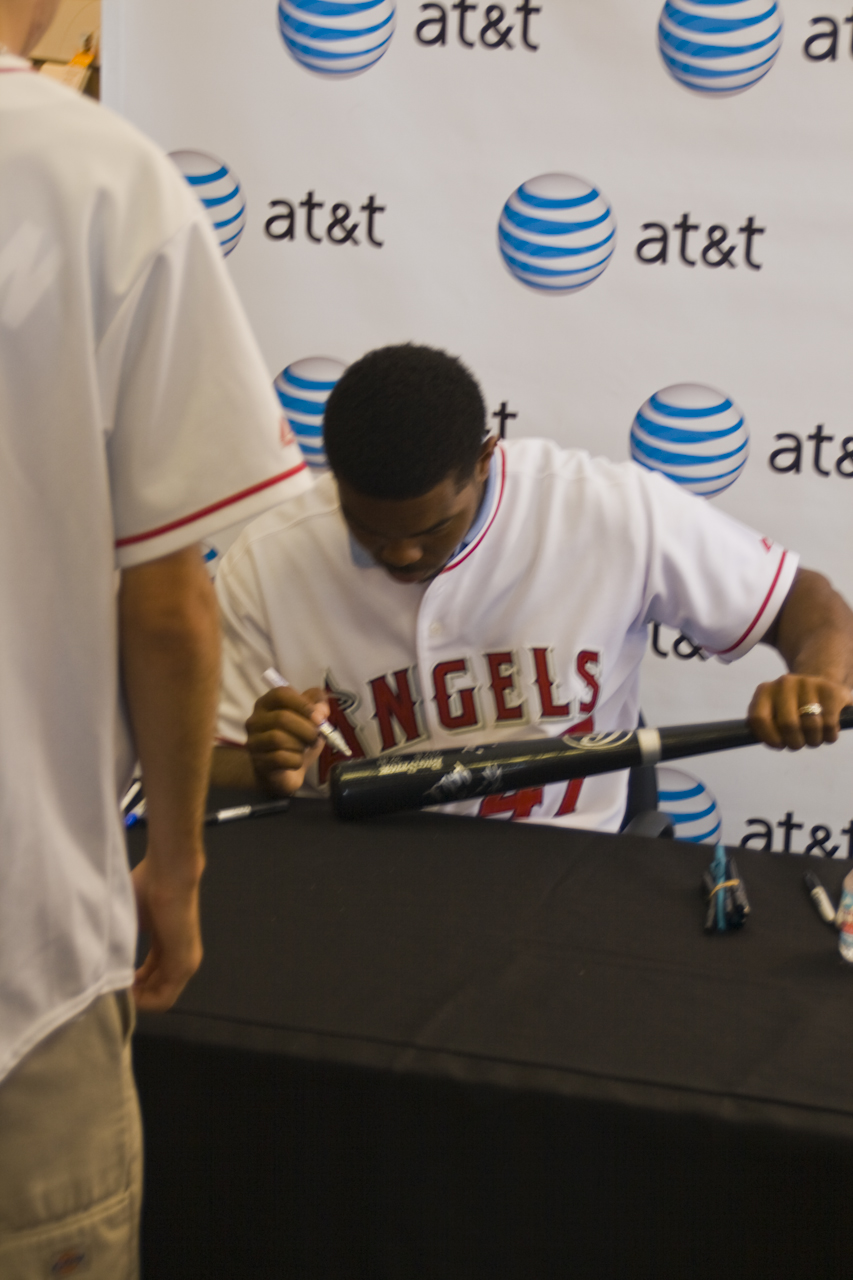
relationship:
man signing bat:
[209, 339, 853, 835] [294, 700, 850, 808]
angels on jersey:
[311, 654, 618, 761] [213, 437, 802, 835]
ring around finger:
[799, 701, 823, 715] [791, 677, 820, 744]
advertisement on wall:
[468, 152, 781, 303] [97, 52, 852, 867]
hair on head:
[322, 336, 493, 509] [319, 338, 513, 589]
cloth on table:
[107, 778, 850, 1277] [76, 765, 842, 1244]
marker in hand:
[259, 665, 357, 761] [239, 680, 337, 789]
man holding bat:
[192, 316, 850, 859] [325, 691, 851, 831]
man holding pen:
[192, 316, 850, 859] [248, 647, 364, 757]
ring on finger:
[799, 701, 823, 715] [799, 686, 828, 740]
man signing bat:
[209, 339, 853, 835] [325, 691, 851, 831]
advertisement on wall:
[496, 173, 764, 295] [97, 52, 852, 867]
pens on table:
[696, 837, 760, 935] [122, 775, 845, 1150]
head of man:
[319, 338, 513, 589] [192, 316, 850, 859]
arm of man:
[632, 470, 851, 678] [209, 339, 853, 835]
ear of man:
[475, 422, 504, 485] [209, 339, 853, 835]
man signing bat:
[209, 339, 853, 835] [333, 678, 852, 816]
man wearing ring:
[209, 339, 853, 835] [795, 694, 824, 717]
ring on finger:
[801, 699, 825, 723] [796, 676, 822, 743]